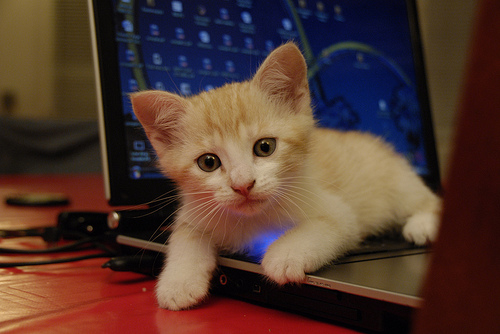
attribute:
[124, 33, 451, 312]
cat — white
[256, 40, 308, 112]
cat ears — pink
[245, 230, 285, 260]
light — shining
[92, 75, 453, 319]
kitten — back paw 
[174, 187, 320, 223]
kittys whiskers — abundant